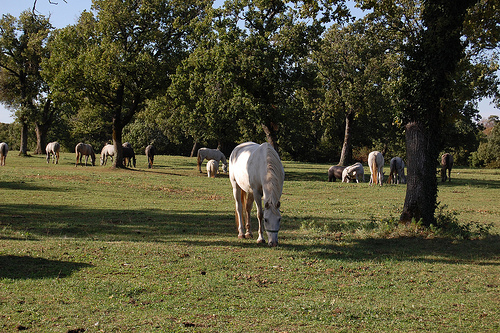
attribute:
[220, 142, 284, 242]
horse — white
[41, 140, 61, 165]
horse — tall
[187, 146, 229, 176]
horse — grouped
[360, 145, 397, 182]
horse — grouped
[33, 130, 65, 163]
horse — grouped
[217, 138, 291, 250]
horse — tall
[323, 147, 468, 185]
horse — tall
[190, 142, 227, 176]
horse — tall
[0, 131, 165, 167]
horse — tall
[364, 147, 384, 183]
horse — white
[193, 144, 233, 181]
horse — tall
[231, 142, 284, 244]
horse — white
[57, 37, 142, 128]
tree — green, large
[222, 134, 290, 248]
horse — white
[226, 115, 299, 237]
horse — white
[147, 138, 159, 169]
horse — tall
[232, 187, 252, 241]
legs — back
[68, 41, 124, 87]
leaves — green